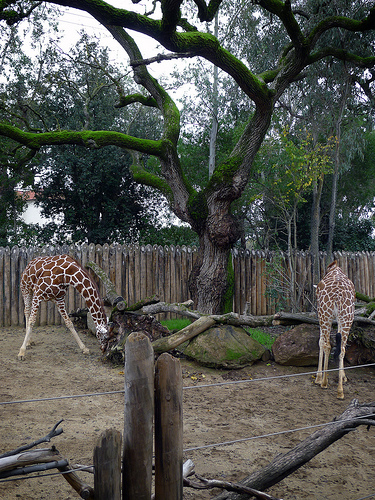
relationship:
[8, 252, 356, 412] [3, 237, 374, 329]
giraffes in fence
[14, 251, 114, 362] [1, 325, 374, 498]
giraffe in fence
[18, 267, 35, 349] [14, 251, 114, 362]
back legs of giraffe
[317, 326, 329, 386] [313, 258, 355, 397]
front leg of giraffe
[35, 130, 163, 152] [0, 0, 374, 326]
moss on tree